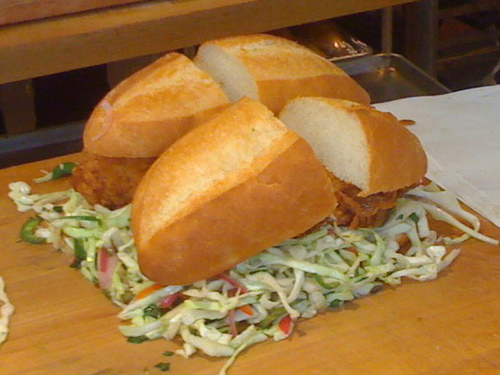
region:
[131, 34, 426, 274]
the breads are cut in half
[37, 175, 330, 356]
vegetables under the bread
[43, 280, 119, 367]
the chopping board is brown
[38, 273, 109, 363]
the chopping board is made of wood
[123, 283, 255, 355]
the lettuce are chopped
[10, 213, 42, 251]
the pepper is green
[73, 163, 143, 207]
the meat is brown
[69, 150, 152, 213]
the meat is under the bread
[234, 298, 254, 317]
the carrot is orange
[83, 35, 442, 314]
there are two breads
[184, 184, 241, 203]
crust on top of bread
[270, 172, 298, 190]
small indent in bread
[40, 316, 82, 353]
faint lines on brown cutting board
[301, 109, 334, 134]
white inside of bread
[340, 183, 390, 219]
crispy fried meat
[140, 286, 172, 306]
small piece of orange carrot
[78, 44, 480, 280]
large sections of sandwiches on board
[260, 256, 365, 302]
chopped lettuce on board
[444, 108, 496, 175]
white piece of napkin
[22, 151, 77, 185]
edge of cutting surface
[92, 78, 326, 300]
piece of french bread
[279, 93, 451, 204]
piece of french bread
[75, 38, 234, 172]
piece of french bread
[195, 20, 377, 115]
piece of french bread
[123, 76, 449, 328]
large sandwich on french bread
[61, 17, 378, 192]
large sandwich on french bread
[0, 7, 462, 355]
two sandwiches on a bed of lettuce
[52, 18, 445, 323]
two french bread sandwiches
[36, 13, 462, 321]
two french bread sandwiches on a bed of lettuce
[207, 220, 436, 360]
a pile of lettuce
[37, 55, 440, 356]
a meal on the table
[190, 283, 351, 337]
shredded cabbage in a salad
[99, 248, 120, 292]
purple onion pieces in a salad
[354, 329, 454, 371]
a brown wooden table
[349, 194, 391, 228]
bacon strips on top of slaw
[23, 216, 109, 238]
green peppers in slaw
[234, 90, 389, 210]
sliced bread on top of salad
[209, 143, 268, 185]
golden brown bread crust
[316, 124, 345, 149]
soft white inside of bread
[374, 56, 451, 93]
a metal tray on a chair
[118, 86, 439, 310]
Bread is cut in half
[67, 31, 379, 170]
Bread is cut in half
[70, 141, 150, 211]
Piece of meat under bread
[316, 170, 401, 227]
Piece of meat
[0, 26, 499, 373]
Sandwich on a table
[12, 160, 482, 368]
Cabbage cut in small pieces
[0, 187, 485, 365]
Cabbage is under bread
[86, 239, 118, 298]
Slice of onion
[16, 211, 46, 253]
Slice of green pepper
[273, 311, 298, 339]
Piece of carrot